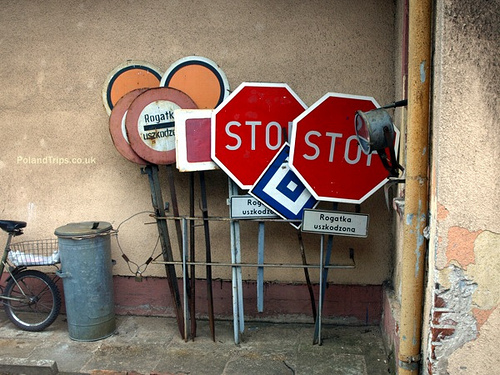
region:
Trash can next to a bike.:
[54, 222, 125, 320]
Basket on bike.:
[11, 240, 56, 260]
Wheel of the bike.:
[9, 276, 56, 317]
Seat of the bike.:
[2, 209, 33, 242]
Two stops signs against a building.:
[228, 100, 355, 165]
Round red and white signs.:
[113, 95, 173, 167]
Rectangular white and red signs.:
[177, 109, 209, 171]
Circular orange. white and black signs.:
[119, 66, 221, 85]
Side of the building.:
[43, 115, 108, 215]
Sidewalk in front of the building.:
[132, 350, 347, 374]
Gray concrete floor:
[114, 343, 354, 369]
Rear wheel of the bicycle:
[3, 268, 63, 331]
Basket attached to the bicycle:
[10, 238, 62, 267]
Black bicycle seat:
[1, 211, 30, 243]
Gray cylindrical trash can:
[53, 211, 133, 348]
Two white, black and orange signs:
[99, 55, 226, 106]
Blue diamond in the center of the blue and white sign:
[273, 169, 304, 201]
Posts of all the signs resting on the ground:
[163, 271, 332, 346]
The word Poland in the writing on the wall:
[13, 151, 49, 166]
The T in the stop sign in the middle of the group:
[243, 118, 265, 155]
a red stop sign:
[223, 101, 278, 166]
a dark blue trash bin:
[61, 223, 112, 323]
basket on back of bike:
[18, 236, 53, 262]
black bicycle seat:
[3, 218, 21, 233]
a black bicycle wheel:
[11, 276, 53, 329]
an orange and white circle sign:
[168, 48, 221, 98]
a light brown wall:
[11, 23, 68, 133]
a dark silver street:
[130, 328, 179, 373]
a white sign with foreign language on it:
[303, 212, 364, 246]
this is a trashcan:
[53, 224, 120, 339]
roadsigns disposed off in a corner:
[103, 58, 402, 210]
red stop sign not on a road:
[208, 79, 314, 184]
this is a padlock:
[134, 268, 144, 283]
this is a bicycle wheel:
[6, 270, 65, 332]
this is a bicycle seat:
[1, 218, 28, 238]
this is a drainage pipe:
[396, 134, 431, 374]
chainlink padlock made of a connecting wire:
[116, 212, 166, 272]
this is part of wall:
[439, 157, 497, 374]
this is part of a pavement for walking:
[70, 341, 189, 372]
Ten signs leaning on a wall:
[93, 35, 405, 353]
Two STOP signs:
[211, 81, 393, 352]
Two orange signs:
[96, 50, 233, 129]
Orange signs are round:
[86, 50, 231, 131]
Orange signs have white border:
[96, 52, 232, 122]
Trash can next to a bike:
[50, 213, 125, 343]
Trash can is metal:
[47, 215, 129, 352]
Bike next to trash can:
[2, 215, 67, 337]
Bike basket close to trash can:
[10, 235, 60, 270]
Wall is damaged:
[418, 18, 497, 373]